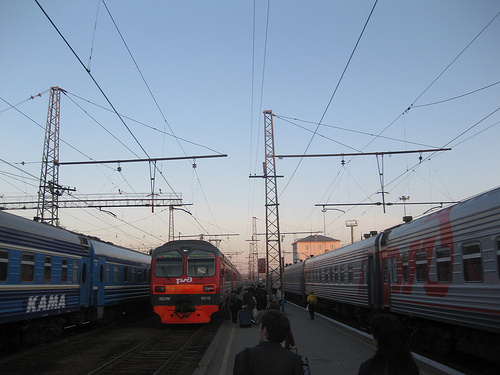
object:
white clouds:
[136, 0, 219, 35]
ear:
[263, 326, 268, 336]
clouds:
[167, 67, 312, 102]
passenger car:
[374, 182, 500, 337]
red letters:
[356, 205, 456, 298]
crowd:
[227, 283, 286, 327]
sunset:
[88, 233, 423, 275]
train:
[271, 185, 500, 330]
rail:
[83, 290, 230, 374]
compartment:
[87, 239, 95, 307]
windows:
[11, 253, 86, 286]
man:
[230, 309, 311, 375]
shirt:
[305, 294, 318, 300]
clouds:
[378, 202, 417, 220]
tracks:
[282, 290, 465, 374]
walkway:
[190, 274, 470, 374]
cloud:
[318, 203, 410, 248]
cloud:
[70, 207, 299, 263]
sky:
[4, 0, 494, 272]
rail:
[262, 110, 284, 315]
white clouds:
[331, 0, 356, 20]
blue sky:
[0, 0, 499, 275]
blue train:
[0, 210, 155, 349]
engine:
[148, 239, 227, 326]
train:
[152, 237, 243, 324]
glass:
[152, 249, 215, 279]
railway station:
[0, 155, 499, 374]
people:
[233, 300, 253, 329]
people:
[257, 283, 267, 310]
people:
[226, 294, 241, 322]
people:
[243, 284, 253, 306]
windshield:
[154, 248, 183, 277]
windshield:
[185, 247, 216, 277]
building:
[292, 231, 342, 266]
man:
[307, 290, 318, 321]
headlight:
[152, 285, 214, 293]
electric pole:
[259, 109, 284, 309]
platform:
[173, 265, 475, 375]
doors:
[77, 256, 110, 308]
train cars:
[2, 211, 154, 337]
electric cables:
[0, 0, 499, 270]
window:
[155, 257, 181, 277]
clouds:
[442, 131, 494, 183]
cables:
[268, 107, 440, 155]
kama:
[21, 290, 72, 315]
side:
[0, 210, 87, 326]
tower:
[263, 111, 284, 310]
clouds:
[30, 135, 219, 175]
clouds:
[319, 78, 378, 112]